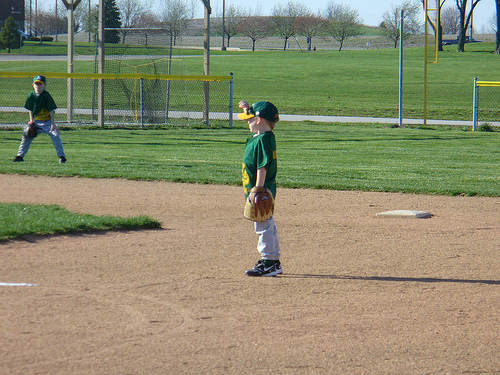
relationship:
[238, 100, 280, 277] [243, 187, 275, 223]
child has glove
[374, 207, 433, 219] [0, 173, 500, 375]
base in dirt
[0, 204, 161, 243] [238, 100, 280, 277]
grass by child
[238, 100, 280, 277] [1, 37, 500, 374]
child in field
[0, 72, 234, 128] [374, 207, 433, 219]
fence by base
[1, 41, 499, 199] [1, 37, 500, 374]
grass in field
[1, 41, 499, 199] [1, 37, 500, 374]
grass by field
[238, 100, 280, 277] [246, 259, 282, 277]
child has cleats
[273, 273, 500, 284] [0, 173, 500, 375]
shadow in dirt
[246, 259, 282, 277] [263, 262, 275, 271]
cleats has symbol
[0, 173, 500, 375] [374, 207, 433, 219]
dirt under base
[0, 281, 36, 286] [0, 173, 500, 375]
line on dirt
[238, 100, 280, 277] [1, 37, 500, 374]
child on field